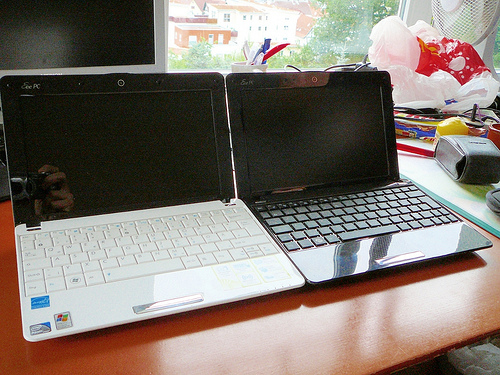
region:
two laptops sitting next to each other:
[15, 61, 475, 316]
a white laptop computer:
[4, 55, 269, 339]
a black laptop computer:
[227, 61, 462, 278]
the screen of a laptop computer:
[24, 91, 209, 211]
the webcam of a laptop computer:
[102, 75, 139, 99]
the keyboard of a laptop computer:
[32, 228, 256, 270]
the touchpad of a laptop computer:
[124, 286, 214, 311]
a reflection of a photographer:
[4, 163, 79, 215]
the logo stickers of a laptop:
[31, 296, 101, 336]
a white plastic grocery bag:
[372, 15, 497, 102]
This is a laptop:
[225, 52, 497, 296]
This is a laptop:
[12, 46, 249, 372]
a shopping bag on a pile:
[367, 15, 499, 114]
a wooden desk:
[0, 169, 499, 374]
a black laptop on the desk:
[225, 70, 493, 286]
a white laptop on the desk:
[0, 71, 305, 341]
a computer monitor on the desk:
[0, 0, 167, 80]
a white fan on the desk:
[430, 0, 498, 82]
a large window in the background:
[166, 0, 498, 92]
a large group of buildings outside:
[167, 0, 328, 60]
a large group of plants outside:
[167, 0, 499, 69]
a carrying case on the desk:
[433, 134, 498, 184]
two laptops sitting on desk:
[0, 67, 492, 344]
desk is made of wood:
[1, 188, 498, 373]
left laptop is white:
[0, 71, 305, 345]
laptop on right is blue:
[227, 66, 493, 286]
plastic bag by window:
[368, 17, 498, 109]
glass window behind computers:
[168, 0, 498, 89]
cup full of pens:
[226, 33, 289, 73]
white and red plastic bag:
[364, 15, 499, 111]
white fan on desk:
[430, 0, 499, 82]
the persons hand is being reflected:
[6, 162, 73, 214]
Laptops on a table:
[0, 61, 495, 343]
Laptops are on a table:
[0, 62, 495, 345]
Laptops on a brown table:
[0, 57, 495, 347]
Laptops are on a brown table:
[0, 63, 497, 345]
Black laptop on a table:
[220, 65, 495, 280]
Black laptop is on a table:
[224, 67, 494, 287]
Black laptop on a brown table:
[223, 65, 494, 292]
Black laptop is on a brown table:
[224, 67, 490, 288]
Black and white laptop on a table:
[0, 70, 310, 345]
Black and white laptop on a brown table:
[0, 68, 309, 345]